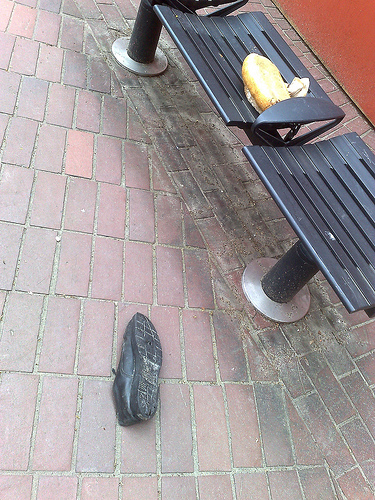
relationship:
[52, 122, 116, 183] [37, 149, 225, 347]
red brick in ground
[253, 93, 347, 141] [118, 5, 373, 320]
arm of bench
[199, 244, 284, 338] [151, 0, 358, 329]
dirt under bench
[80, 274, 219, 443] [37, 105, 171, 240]
shoe on ground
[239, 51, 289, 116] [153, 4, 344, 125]
sandwich on bench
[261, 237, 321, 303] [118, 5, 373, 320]
pole holding bench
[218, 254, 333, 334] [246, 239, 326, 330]
plate around post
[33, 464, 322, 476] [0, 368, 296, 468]
cement grout around bricks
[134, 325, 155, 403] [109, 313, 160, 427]
sole of shoe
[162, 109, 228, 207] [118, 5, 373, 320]
bricks under bench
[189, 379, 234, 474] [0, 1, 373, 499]
brick in ground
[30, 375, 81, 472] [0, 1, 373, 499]
brick in ground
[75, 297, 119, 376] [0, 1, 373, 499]
brick in ground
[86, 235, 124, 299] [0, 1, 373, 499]
brick in ground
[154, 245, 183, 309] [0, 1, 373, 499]
brick in ground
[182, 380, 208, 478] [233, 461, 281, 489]
gray line on ground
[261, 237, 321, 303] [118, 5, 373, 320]
pole under bench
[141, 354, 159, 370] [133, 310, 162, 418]
dirt on sole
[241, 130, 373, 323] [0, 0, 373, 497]
bench on sidewalk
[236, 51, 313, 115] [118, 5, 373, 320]
trash on bench